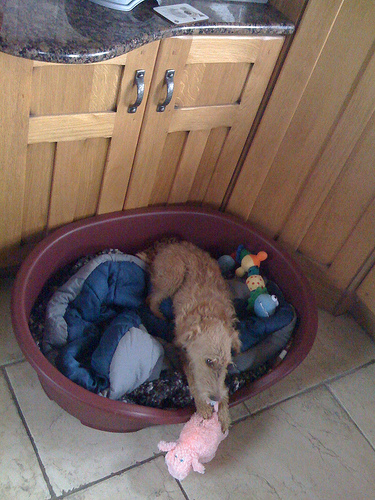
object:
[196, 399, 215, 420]
paw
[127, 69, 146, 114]
handle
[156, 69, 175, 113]
handle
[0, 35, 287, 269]
cabinet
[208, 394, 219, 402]
nose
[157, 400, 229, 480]
pig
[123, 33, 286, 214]
door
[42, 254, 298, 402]
bed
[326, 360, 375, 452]
tile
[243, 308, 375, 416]
tile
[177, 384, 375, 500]
tile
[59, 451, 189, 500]
tile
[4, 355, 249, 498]
tile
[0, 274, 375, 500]
floor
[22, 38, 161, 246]
doors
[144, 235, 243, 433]
brown dog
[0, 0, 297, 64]
counter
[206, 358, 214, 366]
eye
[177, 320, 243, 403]
head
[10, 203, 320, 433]
basket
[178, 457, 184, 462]
eye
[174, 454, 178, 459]
eye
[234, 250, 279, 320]
playtoy